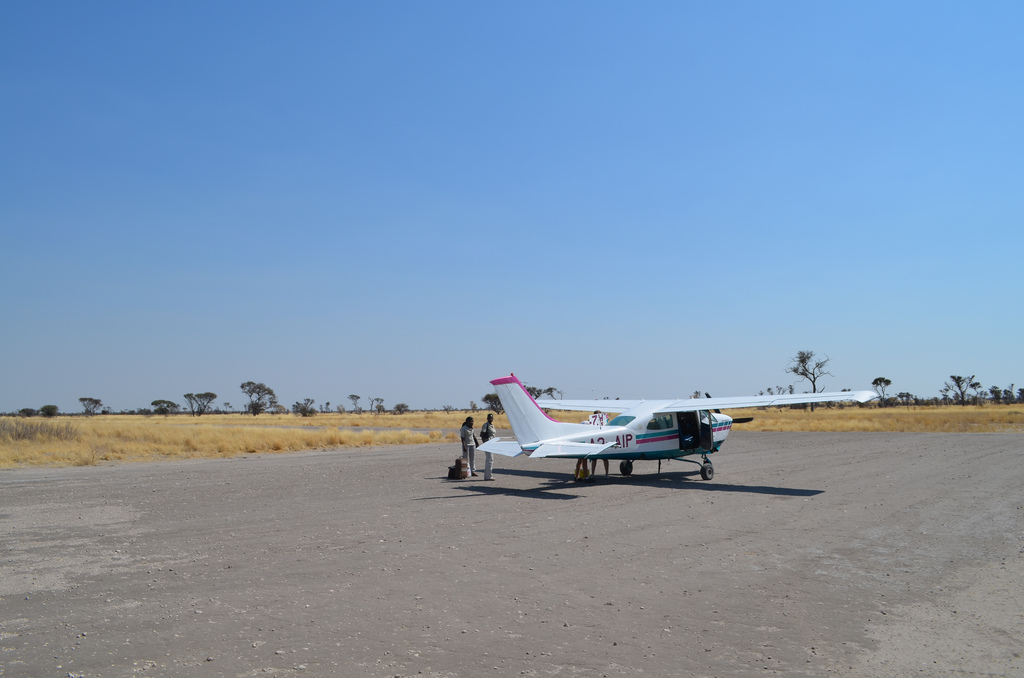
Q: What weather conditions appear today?
A: It is clear.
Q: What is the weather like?
A: It is clear.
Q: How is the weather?
A: It is clear.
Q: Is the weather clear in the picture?
A: Yes, it is clear.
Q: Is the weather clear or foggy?
A: It is clear.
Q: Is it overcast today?
A: No, it is clear.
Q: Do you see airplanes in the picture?
A: Yes, there is an airplane.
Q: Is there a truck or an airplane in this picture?
A: Yes, there is an airplane.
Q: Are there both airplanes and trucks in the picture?
A: No, there is an airplane but no trucks.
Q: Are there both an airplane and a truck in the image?
A: No, there is an airplane but no trucks.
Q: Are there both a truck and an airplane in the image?
A: No, there is an airplane but no trucks.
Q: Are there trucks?
A: No, there are no trucks.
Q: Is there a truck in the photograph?
A: No, there are no trucks.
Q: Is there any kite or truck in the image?
A: No, there are no trucks or kites.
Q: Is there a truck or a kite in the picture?
A: No, there are no trucks or kites.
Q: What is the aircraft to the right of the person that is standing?
A: The aircraft is an airplane.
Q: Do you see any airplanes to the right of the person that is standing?
A: Yes, there is an airplane to the right of the person.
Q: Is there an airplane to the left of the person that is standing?
A: No, the airplane is to the right of the person.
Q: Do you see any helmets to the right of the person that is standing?
A: No, there is an airplane to the right of the person.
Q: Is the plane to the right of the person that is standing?
A: Yes, the plane is to the right of the person.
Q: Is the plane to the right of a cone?
A: No, the plane is to the right of the person.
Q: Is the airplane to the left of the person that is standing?
A: No, the airplane is to the right of the person.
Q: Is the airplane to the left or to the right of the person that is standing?
A: The airplane is to the right of the person.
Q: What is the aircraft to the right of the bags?
A: The aircraft is an airplane.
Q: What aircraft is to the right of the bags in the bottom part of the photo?
A: The aircraft is an airplane.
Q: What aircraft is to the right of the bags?
A: The aircraft is an airplane.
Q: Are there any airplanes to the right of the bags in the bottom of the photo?
A: Yes, there is an airplane to the right of the bags.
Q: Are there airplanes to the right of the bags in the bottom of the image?
A: Yes, there is an airplane to the right of the bags.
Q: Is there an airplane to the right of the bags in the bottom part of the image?
A: Yes, there is an airplane to the right of the bags.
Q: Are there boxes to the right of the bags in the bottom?
A: No, there is an airplane to the right of the bags.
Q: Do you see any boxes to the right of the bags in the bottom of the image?
A: No, there is an airplane to the right of the bags.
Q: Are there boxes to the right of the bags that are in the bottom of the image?
A: No, there is an airplane to the right of the bags.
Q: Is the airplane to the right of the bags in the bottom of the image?
A: Yes, the airplane is to the right of the bags.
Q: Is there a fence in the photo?
A: No, there are no fences.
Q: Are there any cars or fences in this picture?
A: No, there are no fences or cars.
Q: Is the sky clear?
A: Yes, the sky is clear.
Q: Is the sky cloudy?
A: No, the sky is clear.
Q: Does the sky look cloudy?
A: No, the sky is clear.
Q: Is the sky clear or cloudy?
A: The sky is clear.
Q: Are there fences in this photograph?
A: No, there are no fences.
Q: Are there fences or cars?
A: No, there are no fences or cars.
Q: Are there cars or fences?
A: No, there are no fences or cars.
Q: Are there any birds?
A: No, there are no birds.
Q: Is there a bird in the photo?
A: No, there are no birds.